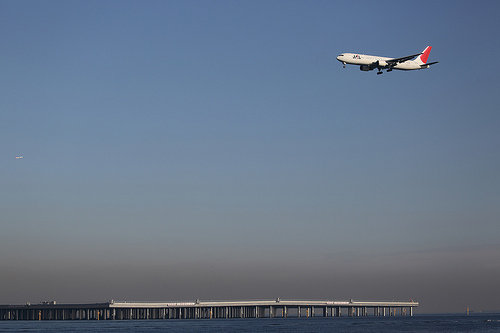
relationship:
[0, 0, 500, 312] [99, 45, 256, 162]
clouds in sky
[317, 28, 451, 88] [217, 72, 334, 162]
plane flies in sky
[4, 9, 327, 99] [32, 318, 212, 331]
sky over ocean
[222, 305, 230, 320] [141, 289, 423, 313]
wood post on pier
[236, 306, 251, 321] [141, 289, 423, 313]
wood post on pier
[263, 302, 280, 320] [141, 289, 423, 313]
wood post on pier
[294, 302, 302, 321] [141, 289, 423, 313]
wood post on pier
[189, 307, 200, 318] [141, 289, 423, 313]
wood post on pier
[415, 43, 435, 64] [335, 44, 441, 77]
tail on plane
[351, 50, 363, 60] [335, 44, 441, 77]
logo on plane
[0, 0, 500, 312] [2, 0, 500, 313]
clouds in sky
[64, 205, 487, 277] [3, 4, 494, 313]
clouds in sky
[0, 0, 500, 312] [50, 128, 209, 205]
clouds in sky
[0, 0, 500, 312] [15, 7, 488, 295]
clouds in sky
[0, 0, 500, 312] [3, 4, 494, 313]
clouds in sky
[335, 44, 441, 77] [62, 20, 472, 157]
plane in air